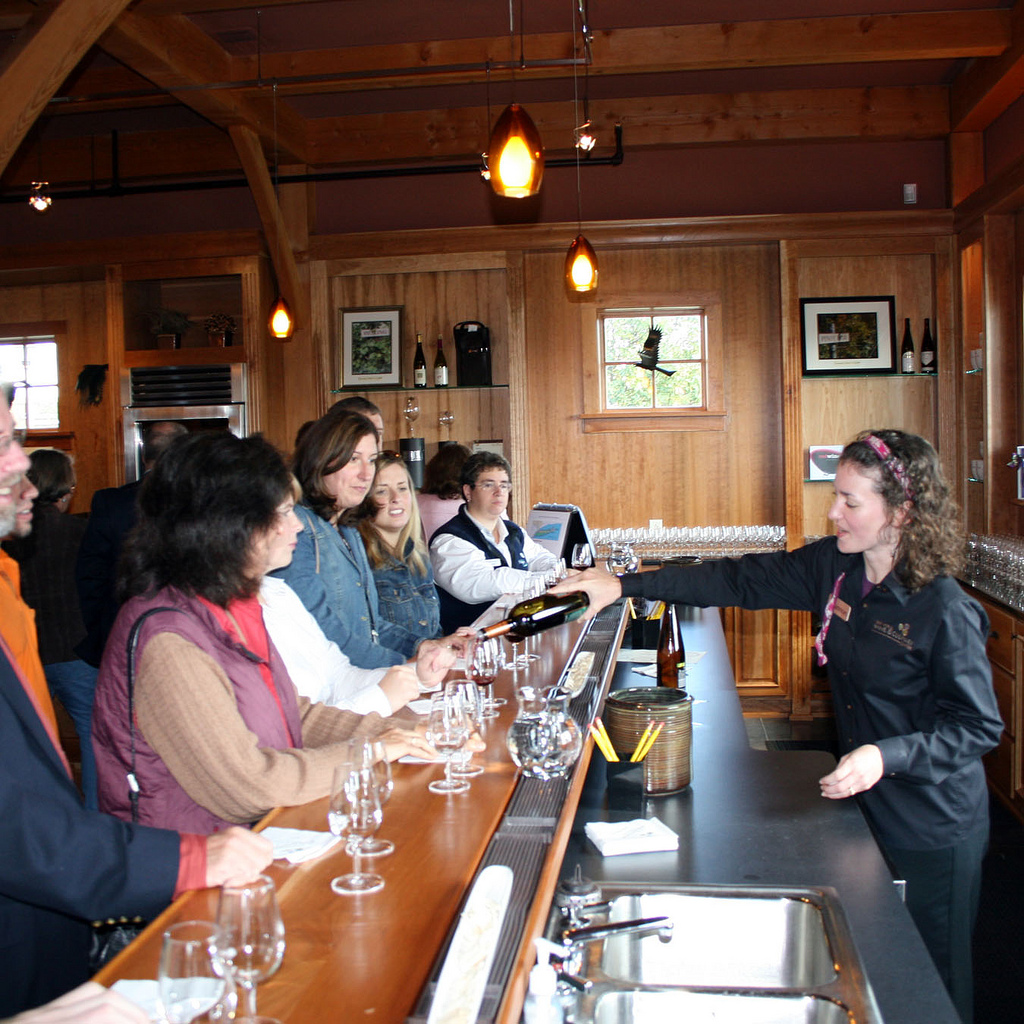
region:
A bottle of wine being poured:
[474, 590, 585, 633]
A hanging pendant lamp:
[490, 6, 542, 199]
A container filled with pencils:
[586, 713, 666, 813]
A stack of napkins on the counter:
[582, 815, 681, 867]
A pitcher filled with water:
[509, 685, 582, 785]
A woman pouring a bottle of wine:
[548, 426, 1001, 1022]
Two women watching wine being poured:
[297, 410, 434, 671]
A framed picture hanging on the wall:
[801, 295, 894, 379]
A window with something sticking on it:
[594, 300, 709, 411]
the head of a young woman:
[801, 443, 941, 583]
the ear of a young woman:
[871, 470, 947, 560]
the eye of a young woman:
[830, 478, 870, 539]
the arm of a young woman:
[874, 590, 1020, 818]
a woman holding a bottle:
[462, 476, 698, 669]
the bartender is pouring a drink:
[468, 430, 1000, 1022]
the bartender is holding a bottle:
[471, 429, 1004, 1022]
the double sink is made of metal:
[531, 875, 883, 1021]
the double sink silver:
[536, 876, 884, 1022]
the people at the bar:
[1, 2, 1022, 1023]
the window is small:
[574, 290, 726, 436]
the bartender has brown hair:
[548, 427, 1000, 1020]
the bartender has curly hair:
[547, 427, 1003, 1022]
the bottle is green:
[476, 593, 587, 641]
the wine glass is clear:
[327, 762, 385, 896]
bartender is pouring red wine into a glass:
[463, 426, 1005, 1022]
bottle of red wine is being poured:
[473, 587, 591, 642]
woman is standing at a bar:
[273, 408, 407, 666]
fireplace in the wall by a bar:
[118, 361, 252, 483]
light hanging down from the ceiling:
[477, 2, 550, 203]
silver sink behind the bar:
[510, 865, 890, 1022]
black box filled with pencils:
[586, 712, 672, 811]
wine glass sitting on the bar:
[327, 762, 389, 895]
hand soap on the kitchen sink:
[518, 930, 577, 1022]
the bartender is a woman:
[539, 422, 1007, 1023]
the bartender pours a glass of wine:
[469, 427, 1007, 1019]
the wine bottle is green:
[475, 589, 590, 643]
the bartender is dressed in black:
[546, 430, 999, 1023]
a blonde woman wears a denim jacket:
[371, 456, 444, 654]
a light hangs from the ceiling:
[554, 237, 605, 299]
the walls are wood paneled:
[2, 215, 932, 718]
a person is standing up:
[547, 411, 988, 1018]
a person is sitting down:
[4, 392, 277, 985]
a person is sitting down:
[99, 444, 461, 841]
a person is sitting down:
[259, 456, 449, 722]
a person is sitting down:
[290, 412, 424, 672]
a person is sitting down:
[347, 447, 434, 653]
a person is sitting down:
[424, 453, 576, 593]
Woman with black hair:
[95, 418, 427, 839]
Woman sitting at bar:
[106, 436, 397, 813]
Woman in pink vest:
[94, 455, 430, 819]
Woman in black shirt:
[626, 455, 990, 918]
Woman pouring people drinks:
[577, 414, 1015, 899]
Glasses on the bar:
[310, 620, 555, 886]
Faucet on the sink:
[537, 885, 678, 956]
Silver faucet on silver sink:
[547, 901, 697, 968]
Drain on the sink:
[549, 863, 619, 908]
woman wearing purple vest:
[72, 415, 304, 849]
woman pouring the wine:
[587, 392, 987, 1007]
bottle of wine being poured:
[452, 585, 583, 640]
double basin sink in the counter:
[539, 856, 866, 1022]